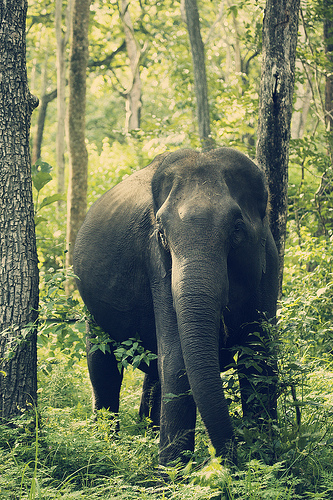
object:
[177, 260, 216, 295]
wrinkles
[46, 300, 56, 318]
leaves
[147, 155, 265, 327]
face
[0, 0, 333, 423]
trees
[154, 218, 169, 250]
eye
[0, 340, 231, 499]
green bush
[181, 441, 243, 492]
ferns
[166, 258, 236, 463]
trunk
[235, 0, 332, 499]
bushes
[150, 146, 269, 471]
head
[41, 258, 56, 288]
leaves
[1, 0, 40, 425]
trunk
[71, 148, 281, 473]
animal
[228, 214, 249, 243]
eye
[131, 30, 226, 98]
leaves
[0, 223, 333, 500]
grass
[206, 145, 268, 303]
ears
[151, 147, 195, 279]
ears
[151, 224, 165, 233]
eyelashes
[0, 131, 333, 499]
ground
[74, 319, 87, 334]
leaf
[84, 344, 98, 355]
leaf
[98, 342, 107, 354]
leaf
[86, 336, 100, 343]
leaf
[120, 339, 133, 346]
leaf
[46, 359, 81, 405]
fern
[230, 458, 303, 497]
fern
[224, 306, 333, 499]
shrub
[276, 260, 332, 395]
shrub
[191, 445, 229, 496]
sunlight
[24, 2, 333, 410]
sunlight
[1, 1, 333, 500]
jungle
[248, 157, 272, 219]
hair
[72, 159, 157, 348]
belly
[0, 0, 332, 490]
woods